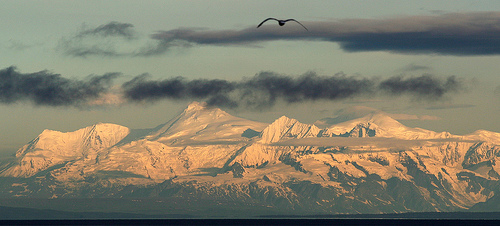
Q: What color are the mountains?
A: White.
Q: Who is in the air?
A: Animal.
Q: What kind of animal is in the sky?
A: Bird.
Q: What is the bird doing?
A: Flying.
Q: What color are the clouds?
A: Gray.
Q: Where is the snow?
A: On the mountain.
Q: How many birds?
A: One.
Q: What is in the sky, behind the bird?
A: Clouds.